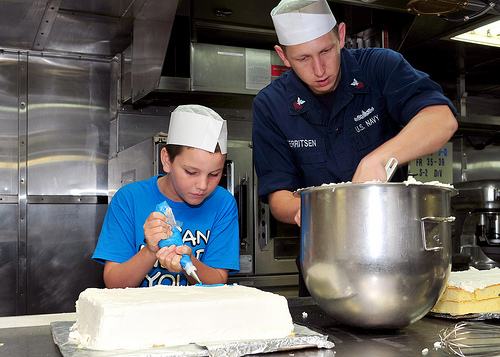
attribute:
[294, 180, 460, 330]
bowl — silver, metal, large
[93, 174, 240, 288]
t-shirt — blue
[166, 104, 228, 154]
hat — white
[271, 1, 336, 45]
hat — white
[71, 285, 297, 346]
cake — white, sitting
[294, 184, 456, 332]
container — silver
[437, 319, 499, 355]
beater — silver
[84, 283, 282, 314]
frosting — blue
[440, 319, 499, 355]
wisk — wire, metal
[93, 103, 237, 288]
chef — apprentice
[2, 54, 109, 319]
sheeting — metal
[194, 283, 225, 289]
frosting — blue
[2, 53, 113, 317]
wall — metal